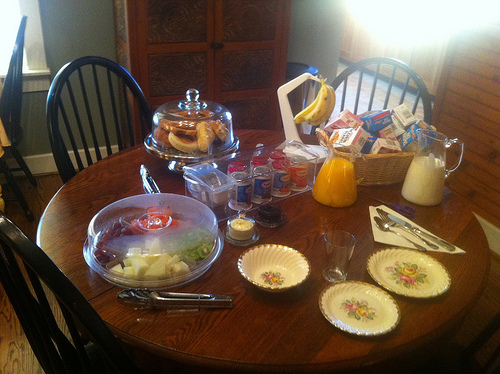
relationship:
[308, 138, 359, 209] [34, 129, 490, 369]
pitcher on kitchen table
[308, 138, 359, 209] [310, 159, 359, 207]
pitcher of juice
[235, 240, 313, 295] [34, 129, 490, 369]
bowl on kitchen table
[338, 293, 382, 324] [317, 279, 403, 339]
flowers on bottom of plate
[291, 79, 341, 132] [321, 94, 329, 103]
bananas with spots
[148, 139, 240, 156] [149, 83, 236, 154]
tray with lid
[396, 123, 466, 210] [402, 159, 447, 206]
pitcher of milk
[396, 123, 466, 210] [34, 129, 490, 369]
pitcher on kitchen table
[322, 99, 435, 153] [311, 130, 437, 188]
cereal boxes in basket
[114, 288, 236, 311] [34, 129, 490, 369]
tongs on kitchen table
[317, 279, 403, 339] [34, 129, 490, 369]
plate on kitchen table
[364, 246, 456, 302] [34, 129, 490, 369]
plate on kitchen table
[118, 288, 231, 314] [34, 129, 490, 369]
tongs on kitchen table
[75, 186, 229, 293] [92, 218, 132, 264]
tray of fruit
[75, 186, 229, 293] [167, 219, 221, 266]
tray of fruit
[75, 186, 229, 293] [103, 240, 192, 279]
tray of cheese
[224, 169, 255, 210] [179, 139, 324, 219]
yogurt in cold case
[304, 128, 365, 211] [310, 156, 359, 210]
pitcher has juice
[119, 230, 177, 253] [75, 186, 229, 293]
cheese in tray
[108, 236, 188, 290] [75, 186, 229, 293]
cheese in tray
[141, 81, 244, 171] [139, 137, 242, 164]
bread on dish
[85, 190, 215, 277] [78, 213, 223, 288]
lid on tray